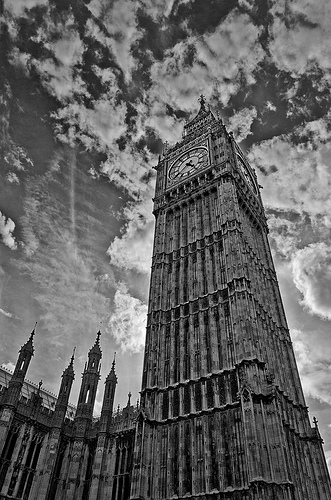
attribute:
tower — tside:
[135, 86, 323, 499]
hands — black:
[185, 156, 196, 170]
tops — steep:
[12, 317, 124, 390]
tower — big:
[125, 66, 316, 456]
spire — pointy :
[199, 93, 208, 115]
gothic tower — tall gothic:
[144, 94, 265, 314]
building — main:
[2, 330, 330, 498]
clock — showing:
[161, 145, 247, 200]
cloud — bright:
[195, 36, 254, 82]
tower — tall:
[141, 98, 328, 489]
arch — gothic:
[209, 183, 217, 203]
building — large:
[1, 94, 330, 498]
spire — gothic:
[7, 321, 37, 410]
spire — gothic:
[53, 346, 75, 429]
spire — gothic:
[73, 321, 102, 434]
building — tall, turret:
[128, 92, 329, 497]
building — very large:
[126, 79, 304, 272]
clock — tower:
[162, 146, 212, 188]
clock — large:
[163, 145, 213, 181]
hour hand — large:
[184, 161, 193, 167]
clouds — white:
[264, 176, 330, 225]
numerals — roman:
[168, 146, 205, 179]